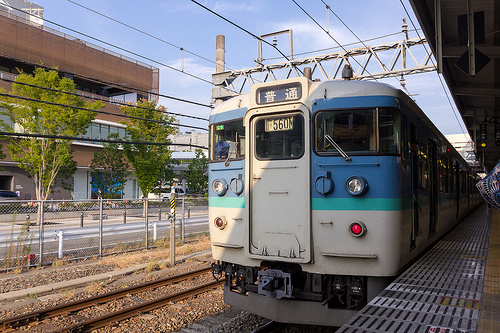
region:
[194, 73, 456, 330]
a blue and white train engine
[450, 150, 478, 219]
a train passenger car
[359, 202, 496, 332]
a passenger boarding platform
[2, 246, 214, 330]
a set of train tracks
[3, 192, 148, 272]
a chain link metal fence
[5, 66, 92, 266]
a short green tree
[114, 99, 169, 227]
a short green tree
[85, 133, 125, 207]
a short green tree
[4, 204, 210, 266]
a paved city street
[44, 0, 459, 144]
a cloudy blue sky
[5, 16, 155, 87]
The building is brown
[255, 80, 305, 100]
An Asian language sign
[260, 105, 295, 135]
The sign says 560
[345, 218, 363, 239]
The light is red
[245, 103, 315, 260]
The door is white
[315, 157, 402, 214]
The paint is blue and green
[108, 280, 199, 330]
The rocks are brown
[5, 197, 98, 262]
A chain link fence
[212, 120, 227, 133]
A green window sticker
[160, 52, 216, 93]
Clouds in the sky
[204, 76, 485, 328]
train is stopped next to platform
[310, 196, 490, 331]
edge of platform is gray metal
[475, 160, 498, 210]
mylat balloon to the right of train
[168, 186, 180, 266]
post next to train track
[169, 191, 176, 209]
black and yellow symbol on post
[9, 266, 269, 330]
brown rocks under train track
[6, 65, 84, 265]
tree behind chain link fence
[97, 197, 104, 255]
metal fence post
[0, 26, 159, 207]
brown building behind fence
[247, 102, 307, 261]
white door on train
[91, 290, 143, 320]
train tracks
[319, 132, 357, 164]
windshield wiper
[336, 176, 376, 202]
lights on the train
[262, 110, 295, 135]
number on the train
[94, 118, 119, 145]
windows on the building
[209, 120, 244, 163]
windshield of the train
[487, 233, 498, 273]
the sidewalk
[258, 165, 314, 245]
door on the train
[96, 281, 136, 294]
tiny rocks on the ground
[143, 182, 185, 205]
a white van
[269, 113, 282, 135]
the black number 5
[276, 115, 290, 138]
the black number 6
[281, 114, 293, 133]
the black number 0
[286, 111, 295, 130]
the black letter m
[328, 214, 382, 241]
this is a red light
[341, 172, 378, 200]
this is a silver light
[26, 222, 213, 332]
these are train tracks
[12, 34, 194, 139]
these are black cables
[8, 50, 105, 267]
this is a tree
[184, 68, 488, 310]
this is the train